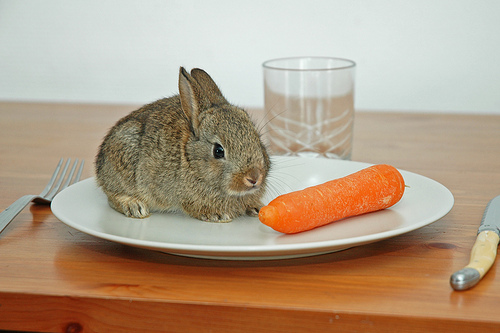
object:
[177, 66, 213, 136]
ear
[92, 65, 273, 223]
bunny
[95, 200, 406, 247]
shadow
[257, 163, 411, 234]
carrot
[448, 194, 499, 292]
knife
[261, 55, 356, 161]
glass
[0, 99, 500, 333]
table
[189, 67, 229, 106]
ears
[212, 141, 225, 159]
eye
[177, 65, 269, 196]
head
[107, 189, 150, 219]
leg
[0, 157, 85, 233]
fork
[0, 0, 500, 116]
wall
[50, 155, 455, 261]
plate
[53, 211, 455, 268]
shadow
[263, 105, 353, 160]
etching